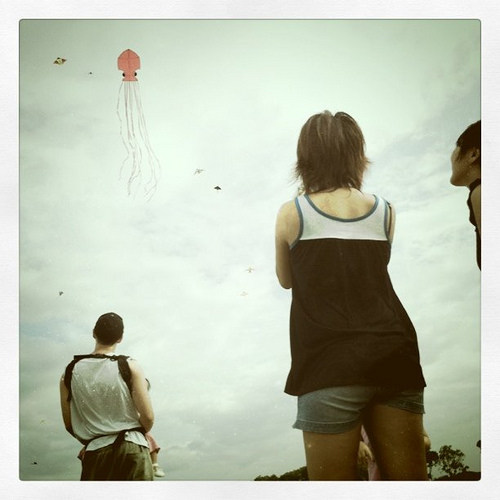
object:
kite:
[115, 48, 163, 203]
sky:
[19, 19, 481, 480]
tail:
[114, 80, 164, 202]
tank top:
[282, 194, 427, 396]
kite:
[53, 56, 68, 66]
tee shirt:
[70, 353, 151, 452]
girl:
[276, 109, 427, 480]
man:
[60, 311, 155, 479]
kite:
[194, 168, 205, 175]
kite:
[213, 185, 221, 191]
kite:
[59, 291, 64, 296]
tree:
[437, 443, 471, 481]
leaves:
[443, 450, 459, 463]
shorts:
[291, 384, 426, 434]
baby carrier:
[63, 352, 146, 454]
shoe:
[151, 462, 164, 477]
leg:
[143, 432, 161, 464]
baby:
[77, 377, 167, 477]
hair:
[287, 108, 373, 198]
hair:
[455, 119, 480, 163]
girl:
[449, 118, 481, 270]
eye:
[122, 72, 126, 78]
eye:
[133, 71, 138, 77]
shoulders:
[117, 354, 141, 377]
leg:
[303, 421, 361, 481]